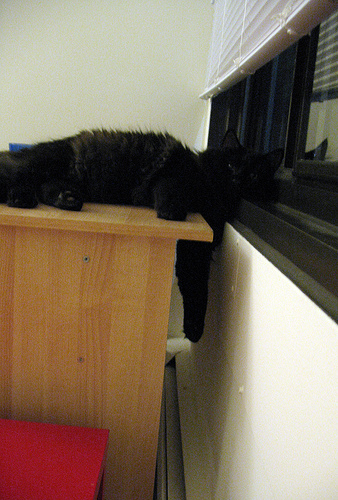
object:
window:
[198, 0, 304, 171]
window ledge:
[204, 178, 336, 313]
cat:
[0, 126, 284, 343]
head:
[203, 132, 287, 204]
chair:
[0, 414, 112, 498]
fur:
[53, 129, 238, 216]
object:
[9, 143, 34, 153]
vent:
[167, 337, 192, 354]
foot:
[52, 181, 84, 211]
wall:
[0, 0, 208, 154]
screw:
[83, 255, 90, 263]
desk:
[0, 203, 213, 498]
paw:
[183, 320, 205, 342]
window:
[292, 20, 338, 176]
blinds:
[312, 11, 337, 93]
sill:
[225, 188, 336, 319]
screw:
[79, 357, 82, 362]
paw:
[153, 199, 189, 221]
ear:
[305, 138, 328, 161]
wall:
[176, 0, 336, 498]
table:
[0, 417, 110, 496]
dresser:
[0, 201, 214, 499]